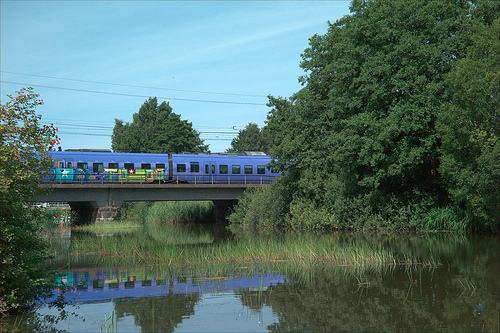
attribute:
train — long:
[9, 148, 296, 188]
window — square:
[191, 161, 200, 175]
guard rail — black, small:
[31, 165, 281, 183]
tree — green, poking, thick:
[266, 0, 482, 245]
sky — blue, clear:
[2, 2, 352, 159]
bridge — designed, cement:
[7, 181, 274, 222]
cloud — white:
[202, 8, 355, 59]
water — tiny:
[12, 221, 484, 327]